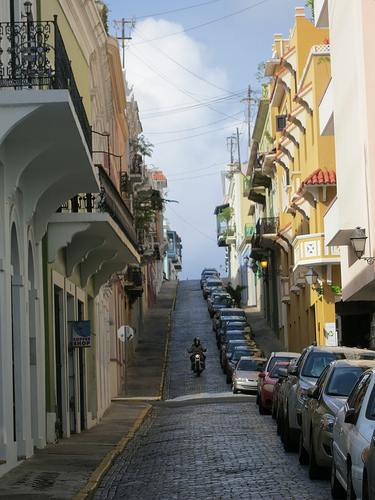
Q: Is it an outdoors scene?
A: Yes, it is outdoors.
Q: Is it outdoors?
A: Yes, it is outdoors.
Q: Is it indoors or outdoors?
A: It is outdoors.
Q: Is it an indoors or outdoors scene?
A: It is outdoors.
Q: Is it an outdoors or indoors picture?
A: It is outdoors.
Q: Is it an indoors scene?
A: No, it is outdoors.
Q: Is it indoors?
A: No, it is outdoors.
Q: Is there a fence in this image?
A: No, there are no fences.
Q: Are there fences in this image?
A: No, there are no fences.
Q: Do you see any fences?
A: No, there are no fences.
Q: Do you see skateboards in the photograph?
A: No, there are no skateboards.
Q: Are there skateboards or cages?
A: No, there are no skateboards or cages.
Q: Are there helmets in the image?
A: No, there are no helmets.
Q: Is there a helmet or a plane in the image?
A: No, there are no helmets or airplanes.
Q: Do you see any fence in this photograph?
A: No, there are no fences.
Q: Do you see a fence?
A: No, there are no fences.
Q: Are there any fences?
A: No, there are no fences.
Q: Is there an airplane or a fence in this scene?
A: No, there are no fences or airplanes.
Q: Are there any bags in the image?
A: No, there are no bags.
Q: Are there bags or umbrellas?
A: No, there are no bags or umbrellas.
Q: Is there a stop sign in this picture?
A: Yes, there is a stop sign.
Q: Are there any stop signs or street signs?
A: Yes, there is a stop sign.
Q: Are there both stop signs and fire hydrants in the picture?
A: No, there is a stop sign but no fire hydrants.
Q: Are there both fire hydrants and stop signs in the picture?
A: No, there is a stop sign but no fire hydrants.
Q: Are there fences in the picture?
A: No, there are no fences.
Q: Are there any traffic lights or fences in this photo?
A: No, there are no fences or traffic lights.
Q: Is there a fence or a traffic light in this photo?
A: No, there are no fences or traffic lights.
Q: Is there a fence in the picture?
A: No, there are no fences.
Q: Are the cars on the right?
A: Yes, the cars are on the right of the image.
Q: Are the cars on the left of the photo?
A: No, the cars are on the right of the image.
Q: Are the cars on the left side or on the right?
A: The cars are on the right of the image.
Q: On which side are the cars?
A: The cars are on the right of the image.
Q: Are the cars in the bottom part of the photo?
A: Yes, the cars are in the bottom of the image.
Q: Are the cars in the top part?
A: No, the cars are in the bottom of the image.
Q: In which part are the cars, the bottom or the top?
A: The cars are in the bottom of the image.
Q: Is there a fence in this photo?
A: No, there are no fences.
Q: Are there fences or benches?
A: No, there are no fences or benches.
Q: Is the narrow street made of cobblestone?
A: Yes, the street is made of cobblestone.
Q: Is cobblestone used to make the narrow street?
A: Yes, the street is made of cobblestone.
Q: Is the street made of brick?
A: No, the street is made of cobblestone.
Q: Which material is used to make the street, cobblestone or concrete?
A: The street is made of cobblestone.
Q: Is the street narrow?
A: Yes, the street is narrow.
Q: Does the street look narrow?
A: Yes, the street is narrow.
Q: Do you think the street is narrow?
A: Yes, the street is narrow.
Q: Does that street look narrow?
A: Yes, the street is narrow.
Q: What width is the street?
A: The street is narrow.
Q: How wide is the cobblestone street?
A: The street is narrow.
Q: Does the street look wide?
A: No, the street is narrow.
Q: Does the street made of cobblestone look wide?
A: No, the street is narrow.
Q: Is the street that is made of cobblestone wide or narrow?
A: The street is narrow.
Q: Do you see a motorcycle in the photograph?
A: Yes, there is a motorcycle.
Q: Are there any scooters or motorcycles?
A: Yes, there is a motorcycle.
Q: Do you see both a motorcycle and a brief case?
A: No, there is a motorcycle but no briefcases.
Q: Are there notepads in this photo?
A: No, there are no notepads.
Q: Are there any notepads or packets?
A: No, there are no notepads or packets.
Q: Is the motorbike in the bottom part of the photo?
A: Yes, the motorbike is in the bottom of the image.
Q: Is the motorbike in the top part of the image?
A: No, the motorbike is in the bottom of the image.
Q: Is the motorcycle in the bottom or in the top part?
A: The motorcycle is in the bottom of the image.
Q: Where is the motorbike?
A: The motorbike is on the street.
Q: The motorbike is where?
A: The motorbike is on the street.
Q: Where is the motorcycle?
A: The motorbike is on the street.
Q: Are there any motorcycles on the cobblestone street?
A: Yes, there is a motorcycle on the street.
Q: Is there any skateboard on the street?
A: No, there is a motorcycle on the street.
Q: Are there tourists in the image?
A: No, there are no tourists.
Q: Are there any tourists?
A: No, there are no tourists.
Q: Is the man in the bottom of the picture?
A: Yes, the man is in the bottom of the image.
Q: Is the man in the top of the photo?
A: No, the man is in the bottom of the image.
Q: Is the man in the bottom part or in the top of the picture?
A: The man is in the bottom of the image.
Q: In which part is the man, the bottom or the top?
A: The man is in the bottom of the image.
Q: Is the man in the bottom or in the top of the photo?
A: The man is in the bottom of the image.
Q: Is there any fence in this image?
A: No, there are no fences.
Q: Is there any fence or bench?
A: No, there are no fences or benches.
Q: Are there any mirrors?
A: Yes, there is a mirror.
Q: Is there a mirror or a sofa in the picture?
A: Yes, there is a mirror.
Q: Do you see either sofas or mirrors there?
A: Yes, there is a mirror.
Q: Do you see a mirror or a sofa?
A: Yes, there is a mirror.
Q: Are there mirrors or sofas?
A: Yes, there is a mirror.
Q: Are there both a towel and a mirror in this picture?
A: No, there is a mirror but no towels.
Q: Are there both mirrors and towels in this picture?
A: No, there is a mirror but no towels.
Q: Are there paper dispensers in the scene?
A: No, there are no paper dispensers.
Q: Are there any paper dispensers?
A: No, there are no paper dispensers.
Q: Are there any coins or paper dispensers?
A: No, there are no paper dispensers or coins.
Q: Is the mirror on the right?
A: Yes, the mirror is on the right of the image.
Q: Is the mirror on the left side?
A: No, the mirror is on the right of the image.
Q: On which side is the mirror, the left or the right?
A: The mirror is on the right of the image.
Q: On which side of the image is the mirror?
A: The mirror is on the right of the image.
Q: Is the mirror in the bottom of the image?
A: Yes, the mirror is in the bottom of the image.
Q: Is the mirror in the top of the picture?
A: No, the mirror is in the bottom of the image.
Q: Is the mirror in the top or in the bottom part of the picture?
A: The mirror is in the bottom of the image.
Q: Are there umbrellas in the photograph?
A: No, there are no umbrellas.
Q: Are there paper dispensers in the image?
A: No, there are no paper dispensers.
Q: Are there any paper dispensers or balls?
A: No, there are no paper dispensers or balls.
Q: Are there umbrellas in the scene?
A: No, there are no umbrellas.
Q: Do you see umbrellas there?
A: No, there are no umbrellas.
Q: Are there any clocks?
A: No, there are no clocks.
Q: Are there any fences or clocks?
A: No, there are no clocks or fences.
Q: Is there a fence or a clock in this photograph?
A: No, there are no clocks or fences.